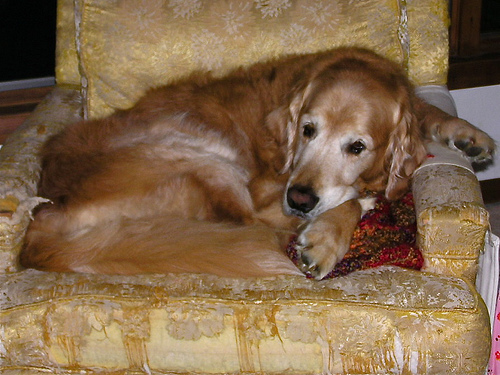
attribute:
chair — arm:
[21, 1, 492, 366]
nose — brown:
[285, 182, 319, 212]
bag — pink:
[351, 186, 418, 282]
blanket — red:
[341, 202, 433, 268]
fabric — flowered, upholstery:
[151, 12, 399, 97]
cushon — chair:
[0, 0, 494, 375]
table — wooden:
[4, 86, 49, 126]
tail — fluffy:
[29, 205, 303, 298]